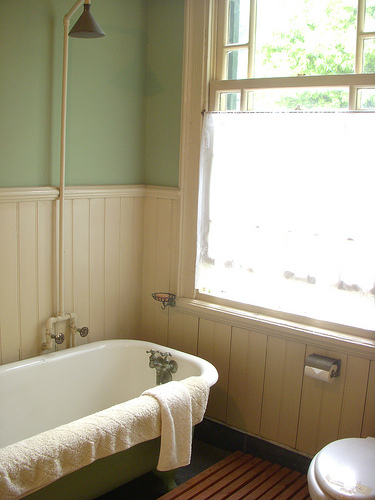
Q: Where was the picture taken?
A: It was taken at the bathroom.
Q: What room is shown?
A: It is a bathroom.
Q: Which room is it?
A: It is a bathroom.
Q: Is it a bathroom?
A: Yes, it is a bathroom.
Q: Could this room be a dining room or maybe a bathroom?
A: It is a bathroom.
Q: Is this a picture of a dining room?
A: No, the picture is showing a bathroom.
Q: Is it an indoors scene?
A: Yes, it is indoors.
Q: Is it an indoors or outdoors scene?
A: It is indoors.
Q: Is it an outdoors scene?
A: No, it is indoors.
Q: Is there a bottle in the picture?
A: No, there are no bottles.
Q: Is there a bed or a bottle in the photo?
A: No, there are no bottles or beds.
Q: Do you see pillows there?
A: No, there are no pillows.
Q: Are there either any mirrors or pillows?
A: No, there are no pillows or mirrors.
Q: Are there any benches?
A: No, there are no benches.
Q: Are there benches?
A: No, there are no benches.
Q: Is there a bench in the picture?
A: No, there are no benches.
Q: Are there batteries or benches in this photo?
A: No, there are no benches or batteries.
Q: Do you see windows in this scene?
A: Yes, there is a window.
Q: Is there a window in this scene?
A: Yes, there is a window.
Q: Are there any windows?
A: Yes, there is a window.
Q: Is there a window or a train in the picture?
A: Yes, there is a window.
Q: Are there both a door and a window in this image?
A: No, there is a window but no doors.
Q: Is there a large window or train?
A: Yes, there is a large window.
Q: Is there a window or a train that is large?
A: Yes, the window is large.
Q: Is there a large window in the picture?
A: Yes, there is a large window.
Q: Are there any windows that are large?
A: Yes, there is a window that is large.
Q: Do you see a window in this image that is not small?
A: Yes, there is a large window.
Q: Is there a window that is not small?
A: Yes, there is a large window.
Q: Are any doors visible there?
A: No, there are no doors.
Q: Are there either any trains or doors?
A: No, there are no doors or trains.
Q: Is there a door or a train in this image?
A: No, there are no doors or trains.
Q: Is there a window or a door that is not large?
A: No, there is a window but it is large.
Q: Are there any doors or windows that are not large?
A: No, there is a window but it is large.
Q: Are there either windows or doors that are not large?
A: No, there is a window but it is large.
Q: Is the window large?
A: Yes, the window is large.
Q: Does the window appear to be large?
A: Yes, the window is large.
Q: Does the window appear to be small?
A: No, the window is large.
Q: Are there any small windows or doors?
A: No, there is a window but it is large.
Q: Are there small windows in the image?
A: No, there is a window but it is large.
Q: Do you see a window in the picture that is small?
A: No, there is a window but it is large.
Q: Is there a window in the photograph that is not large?
A: No, there is a window but it is large.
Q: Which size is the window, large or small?
A: The window is large.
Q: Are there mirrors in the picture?
A: No, there are no mirrors.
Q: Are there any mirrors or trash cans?
A: No, there are no mirrors or trash cans.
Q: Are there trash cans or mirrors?
A: No, there are no mirrors or trash cans.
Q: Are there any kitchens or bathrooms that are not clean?
A: No, there is a bathroom but it is clean.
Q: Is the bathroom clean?
A: Yes, the bathroom is clean.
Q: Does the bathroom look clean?
A: Yes, the bathroom is clean.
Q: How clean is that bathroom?
A: The bathroom is clean.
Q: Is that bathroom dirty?
A: No, the bathroom is clean.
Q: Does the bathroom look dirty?
A: No, the bathroom is clean.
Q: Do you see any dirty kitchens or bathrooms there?
A: No, there is a bathroom but it is clean.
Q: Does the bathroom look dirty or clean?
A: The bathroom is clean.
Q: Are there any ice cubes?
A: No, there are no ice cubes.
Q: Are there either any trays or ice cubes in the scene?
A: No, there are no ice cubes or trays.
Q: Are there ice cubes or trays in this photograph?
A: No, there are no ice cubes or trays.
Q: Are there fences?
A: No, there are no fences.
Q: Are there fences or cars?
A: No, there are no fences or cars.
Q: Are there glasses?
A: No, there are no glasses.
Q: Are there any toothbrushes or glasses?
A: No, there are no glasses or toothbrushes.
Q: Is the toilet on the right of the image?
A: Yes, the toilet is on the right of the image.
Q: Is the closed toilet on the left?
A: No, the toilet is on the right of the image.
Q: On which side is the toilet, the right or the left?
A: The toilet is on the right of the image.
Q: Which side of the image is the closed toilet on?
A: The toilet is on the right of the image.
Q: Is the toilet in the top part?
A: No, the toilet is in the bottom of the image.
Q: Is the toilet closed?
A: Yes, the toilet is closed.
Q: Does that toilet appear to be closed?
A: Yes, the toilet is closed.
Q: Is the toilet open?
A: No, the toilet is closed.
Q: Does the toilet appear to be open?
A: No, the toilet is closed.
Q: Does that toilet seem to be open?
A: No, the toilet is closed.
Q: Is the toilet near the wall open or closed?
A: The toilet is closed.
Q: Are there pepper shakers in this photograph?
A: No, there are no pepper shakers.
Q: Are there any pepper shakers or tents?
A: No, there are no pepper shakers or tents.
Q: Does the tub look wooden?
A: Yes, the tub is wooden.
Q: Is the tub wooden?
A: Yes, the tub is wooden.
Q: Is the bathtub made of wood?
A: Yes, the bathtub is made of wood.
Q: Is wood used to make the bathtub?
A: Yes, the bathtub is made of wood.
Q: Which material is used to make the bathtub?
A: The bathtub is made of wood.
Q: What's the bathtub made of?
A: The bathtub is made of wood.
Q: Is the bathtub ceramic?
A: No, the bathtub is wooden.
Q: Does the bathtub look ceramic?
A: No, the bathtub is wooden.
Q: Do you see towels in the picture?
A: Yes, there is a towel.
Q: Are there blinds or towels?
A: Yes, there is a towel.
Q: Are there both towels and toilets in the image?
A: Yes, there are both a towel and a toilet.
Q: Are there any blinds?
A: No, there are no blinds.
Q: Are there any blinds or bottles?
A: No, there are no blinds or bottles.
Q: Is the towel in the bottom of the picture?
A: Yes, the towel is in the bottom of the image.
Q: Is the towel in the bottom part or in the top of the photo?
A: The towel is in the bottom of the image.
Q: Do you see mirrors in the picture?
A: No, there are no mirrors.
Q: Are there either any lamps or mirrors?
A: No, there are no mirrors or lamps.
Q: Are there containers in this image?
A: No, there are no containers.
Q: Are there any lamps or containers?
A: No, there are no containers or lamps.